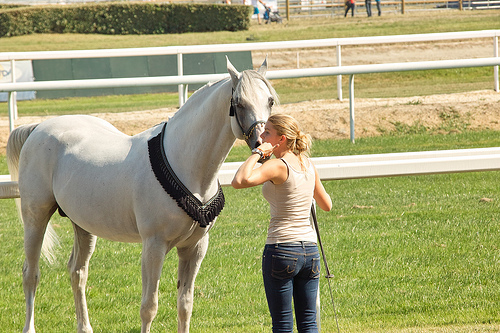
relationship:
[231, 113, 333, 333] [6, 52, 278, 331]
lady with horse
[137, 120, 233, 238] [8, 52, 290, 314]
black collar around horse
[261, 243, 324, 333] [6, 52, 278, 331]
blue jeans of woman with horse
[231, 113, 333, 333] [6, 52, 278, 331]
lady standing with horse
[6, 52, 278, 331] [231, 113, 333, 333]
horse and lady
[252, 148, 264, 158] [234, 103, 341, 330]
watch wrist of woman's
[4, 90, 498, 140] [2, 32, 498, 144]
path between railings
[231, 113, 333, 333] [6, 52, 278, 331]
lady standing in front of horse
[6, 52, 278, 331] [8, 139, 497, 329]
horse standing in grass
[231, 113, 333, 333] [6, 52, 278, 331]
lady standing near horse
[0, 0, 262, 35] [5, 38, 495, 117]
bushes behind rail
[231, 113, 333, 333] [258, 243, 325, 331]
lady wears blue jeans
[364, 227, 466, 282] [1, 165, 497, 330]
grass on field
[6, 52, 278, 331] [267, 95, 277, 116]
horse has eye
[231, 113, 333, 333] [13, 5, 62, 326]
lady face left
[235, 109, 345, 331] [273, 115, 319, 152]
lady has hair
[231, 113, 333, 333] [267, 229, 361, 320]
lady wears jeans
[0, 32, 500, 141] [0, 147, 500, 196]
rail around path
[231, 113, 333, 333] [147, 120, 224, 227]
lady hold bridle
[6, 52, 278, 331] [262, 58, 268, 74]
horse has ear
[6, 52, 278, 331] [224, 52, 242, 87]
horse has ear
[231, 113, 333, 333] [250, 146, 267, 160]
lady wearing watch